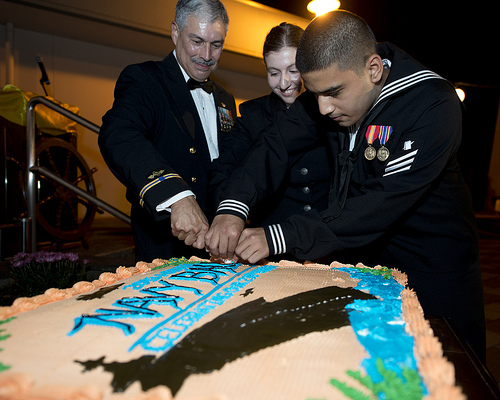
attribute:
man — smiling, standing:
[93, 1, 238, 266]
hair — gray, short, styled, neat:
[170, 0, 232, 33]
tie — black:
[180, 76, 224, 97]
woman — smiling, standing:
[235, 18, 339, 262]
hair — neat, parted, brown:
[258, 18, 315, 80]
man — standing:
[207, 5, 491, 369]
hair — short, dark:
[291, 9, 379, 76]